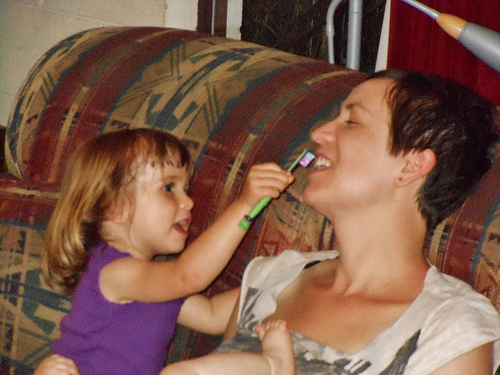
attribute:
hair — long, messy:
[78, 139, 106, 166]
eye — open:
[166, 187, 172, 192]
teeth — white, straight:
[183, 223, 186, 225]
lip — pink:
[183, 232, 187, 239]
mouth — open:
[174, 217, 193, 240]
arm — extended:
[125, 266, 195, 283]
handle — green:
[258, 202, 265, 210]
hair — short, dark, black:
[412, 85, 463, 126]